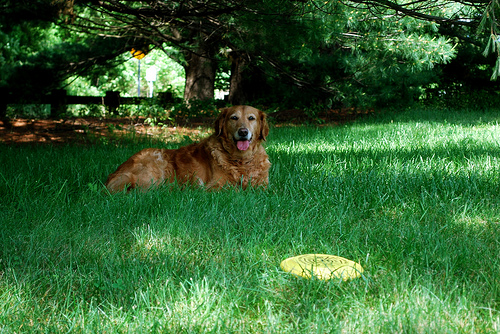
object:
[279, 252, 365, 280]
frisbee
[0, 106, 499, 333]
grass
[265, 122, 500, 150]
spot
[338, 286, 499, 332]
spot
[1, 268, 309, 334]
spot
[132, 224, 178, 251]
spot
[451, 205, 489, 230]
spot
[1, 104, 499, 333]
blade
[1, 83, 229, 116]
fence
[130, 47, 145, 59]
road sign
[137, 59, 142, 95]
post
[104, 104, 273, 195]
dog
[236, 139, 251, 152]
tongue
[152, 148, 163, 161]
spot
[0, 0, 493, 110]
tree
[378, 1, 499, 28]
branch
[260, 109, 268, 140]
ear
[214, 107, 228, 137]
ear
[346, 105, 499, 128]
shadow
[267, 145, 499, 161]
shadow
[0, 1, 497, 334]
scene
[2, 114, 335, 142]
dirt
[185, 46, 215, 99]
trunk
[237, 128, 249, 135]
nose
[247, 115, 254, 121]
eye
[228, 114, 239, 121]
eye